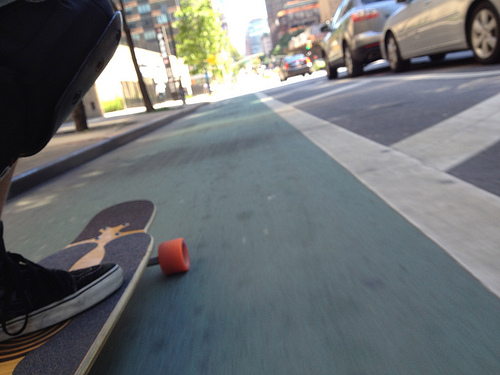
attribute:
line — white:
[292, 112, 480, 229]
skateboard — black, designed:
[2, 197, 192, 373]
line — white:
[413, 108, 488, 165]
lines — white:
[304, 95, 463, 251]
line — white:
[254, 89, 499, 304]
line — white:
[379, 92, 499, 174]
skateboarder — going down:
[0, 193, 195, 373]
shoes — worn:
[6, 224, 126, 374]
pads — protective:
[0, 0, 125, 162]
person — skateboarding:
[1, 1, 125, 332]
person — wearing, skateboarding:
[2, 3, 133, 350]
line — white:
[316, 113, 388, 168]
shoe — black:
[1, 235, 131, 346]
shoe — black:
[0, 217, 124, 344]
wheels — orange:
[129, 230, 219, 288]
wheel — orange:
[159, 238, 189, 274]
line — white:
[250, 85, 498, 282]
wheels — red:
[158, 237, 198, 294]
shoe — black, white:
[2, 248, 127, 348]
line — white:
[306, 100, 466, 195]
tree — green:
[170, 1, 224, 96]